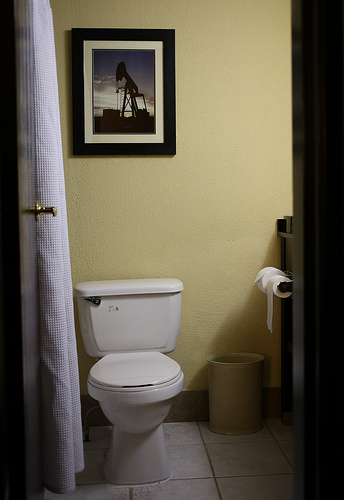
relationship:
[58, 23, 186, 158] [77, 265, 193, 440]
picture behind toilet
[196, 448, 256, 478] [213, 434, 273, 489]
floor has tiles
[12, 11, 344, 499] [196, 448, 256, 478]
bathroom has floor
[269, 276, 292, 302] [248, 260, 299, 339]
toilet paper has two rolls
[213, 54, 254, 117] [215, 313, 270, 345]
wall has shadow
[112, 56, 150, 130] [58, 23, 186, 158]
oil rig in picture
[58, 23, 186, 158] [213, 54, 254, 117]
picture hanging on wall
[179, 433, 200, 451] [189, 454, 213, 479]
flooring has grout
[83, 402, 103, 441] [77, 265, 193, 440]
wire leading to toilet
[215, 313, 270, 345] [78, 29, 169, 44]
shadow on frame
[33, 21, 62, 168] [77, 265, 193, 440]
shower curtain next to toilet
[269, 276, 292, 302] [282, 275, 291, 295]
toilet paper on holders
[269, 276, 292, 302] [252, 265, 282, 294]
toilet paper hanging from toilet rolls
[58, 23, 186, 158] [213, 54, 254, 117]
picture on wall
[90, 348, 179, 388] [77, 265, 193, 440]
lid of toilet